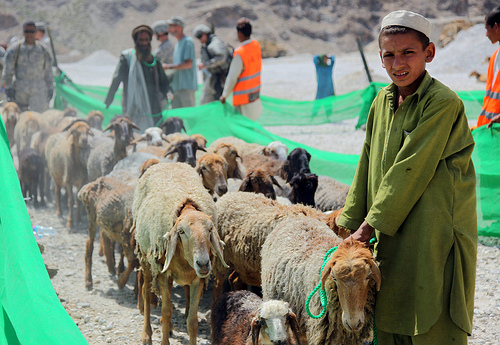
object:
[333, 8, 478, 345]
boy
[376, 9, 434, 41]
hat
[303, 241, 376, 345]
wire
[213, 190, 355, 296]
sheep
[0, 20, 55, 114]
man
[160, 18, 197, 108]
man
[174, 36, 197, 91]
shirt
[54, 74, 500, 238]
fabric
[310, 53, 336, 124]
man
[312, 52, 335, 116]
robe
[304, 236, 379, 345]
green rope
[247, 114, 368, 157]
floor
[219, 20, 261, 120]
man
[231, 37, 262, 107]
vest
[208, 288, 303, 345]
sheep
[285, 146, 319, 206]
sheep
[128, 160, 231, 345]
sheep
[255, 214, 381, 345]
sheep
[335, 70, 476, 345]
clothes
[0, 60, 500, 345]
field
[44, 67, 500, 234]
fences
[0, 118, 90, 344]
fences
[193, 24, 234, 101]
soldier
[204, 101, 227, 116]
helmet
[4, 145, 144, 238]
part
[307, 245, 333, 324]
neck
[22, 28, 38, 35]
sunglasses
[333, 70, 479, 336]
robe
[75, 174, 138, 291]
sheep